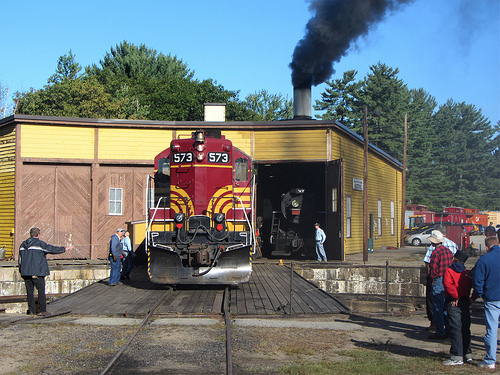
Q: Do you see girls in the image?
A: No, there are no girls.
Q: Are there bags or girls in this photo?
A: No, there are no girls or bags.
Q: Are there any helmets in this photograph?
A: No, there are no helmets.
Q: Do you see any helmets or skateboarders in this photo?
A: No, there are no helmets or skateboarders.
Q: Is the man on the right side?
A: Yes, the man is on the right of the image.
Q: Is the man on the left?
A: No, the man is on the right of the image.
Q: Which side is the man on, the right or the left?
A: The man is on the right of the image.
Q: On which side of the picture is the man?
A: The man is on the right of the image.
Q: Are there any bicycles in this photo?
A: No, there are no bicycles.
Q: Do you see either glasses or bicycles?
A: No, there are no bicycles or glasses.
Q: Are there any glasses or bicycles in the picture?
A: No, there are no bicycles or glasses.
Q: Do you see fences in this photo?
A: No, there are no fences.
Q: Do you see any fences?
A: No, there are no fences.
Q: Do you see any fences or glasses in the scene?
A: No, there are no fences or glasses.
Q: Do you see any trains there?
A: Yes, there is a train.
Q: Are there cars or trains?
A: Yes, there is a train.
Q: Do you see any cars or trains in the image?
A: Yes, there is a train.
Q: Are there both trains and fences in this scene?
A: No, there is a train but no fences.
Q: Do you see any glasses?
A: No, there are no glasses.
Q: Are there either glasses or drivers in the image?
A: No, there are no glasses or drivers.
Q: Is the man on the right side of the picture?
A: Yes, the man is on the right of the image.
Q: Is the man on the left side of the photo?
A: No, the man is on the right of the image.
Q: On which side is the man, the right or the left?
A: The man is on the right of the image.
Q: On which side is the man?
A: The man is on the right of the image.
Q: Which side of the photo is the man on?
A: The man is on the right of the image.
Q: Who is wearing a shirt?
A: The man is wearing a shirt.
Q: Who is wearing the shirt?
A: The man is wearing a shirt.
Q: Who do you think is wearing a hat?
A: The man is wearing a hat.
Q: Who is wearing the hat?
A: The man is wearing a hat.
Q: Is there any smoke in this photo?
A: Yes, there is smoke.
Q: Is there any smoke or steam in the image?
A: Yes, there is smoke.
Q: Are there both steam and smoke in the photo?
A: No, there is smoke but no steam.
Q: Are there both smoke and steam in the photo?
A: No, there is smoke but no steam.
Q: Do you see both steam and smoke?
A: No, there is smoke but no steam.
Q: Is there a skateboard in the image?
A: No, there are no skateboards.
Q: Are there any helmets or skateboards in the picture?
A: No, there are no skateboards or helmets.